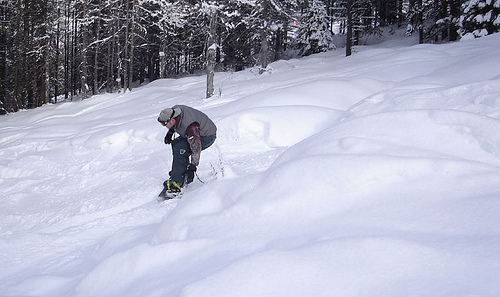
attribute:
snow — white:
[22, 92, 490, 290]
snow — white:
[119, 193, 286, 233]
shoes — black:
[160, 172, 184, 204]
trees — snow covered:
[4, 5, 488, 97]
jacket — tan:
[173, 103, 220, 143]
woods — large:
[0, 0, 500, 119]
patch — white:
[178, 146, 188, 157]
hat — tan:
[155, 102, 184, 129]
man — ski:
[123, 89, 228, 209]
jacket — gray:
[166, 103, 218, 142]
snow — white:
[0, 22, 496, 295]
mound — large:
[295, 114, 384, 182]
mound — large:
[243, 97, 329, 135]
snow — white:
[40, 134, 233, 284]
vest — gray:
[175, 110, 215, 140]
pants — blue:
[172, 133, 217, 178]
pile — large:
[206, 110, 320, 152]